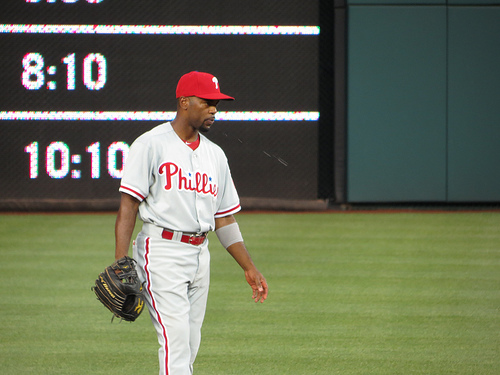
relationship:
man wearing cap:
[115, 70, 269, 374] [176, 69, 236, 103]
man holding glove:
[115, 70, 269, 374] [89, 256, 145, 324]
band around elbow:
[214, 220, 244, 250] [215, 214, 235, 229]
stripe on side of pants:
[142, 233, 170, 374] [131, 222, 210, 373]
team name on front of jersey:
[157, 160, 218, 196] [116, 120, 242, 236]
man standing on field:
[115, 70, 269, 374] [1, 207, 499, 374]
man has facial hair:
[115, 70, 269, 374] [198, 114, 217, 132]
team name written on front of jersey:
[157, 160, 218, 196] [116, 120, 242, 236]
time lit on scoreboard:
[18, 47, 108, 92] [1, 1, 332, 202]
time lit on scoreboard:
[23, 139, 131, 183] [1, 1, 332, 202]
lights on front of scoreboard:
[0, 1, 320, 180] [1, 1, 332, 202]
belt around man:
[159, 229, 207, 246] [115, 70, 269, 374]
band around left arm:
[214, 220, 244, 250] [214, 155, 257, 269]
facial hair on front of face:
[198, 114, 217, 132] [198, 96, 218, 131]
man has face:
[115, 70, 269, 374] [198, 96, 218, 131]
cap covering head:
[176, 69, 236, 103] [174, 71, 232, 133]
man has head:
[115, 70, 269, 374] [174, 71, 232, 133]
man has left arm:
[115, 70, 269, 374] [214, 155, 257, 269]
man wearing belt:
[115, 70, 269, 374] [159, 229, 207, 246]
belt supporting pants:
[159, 229, 207, 246] [131, 222, 210, 373]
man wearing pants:
[115, 70, 269, 374] [131, 222, 210, 373]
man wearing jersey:
[115, 70, 269, 374] [116, 120, 242, 236]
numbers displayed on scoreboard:
[17, 52, 130, 183] [1, 1, 332, 202]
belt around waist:
[159, 229, 207, 246] [138, 217, 213, 246]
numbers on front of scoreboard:
[17, 52, 130, 183] [1, 1, 332, 202]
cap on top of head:
[176, 69, 236, 103] [174, 71, 232, 133]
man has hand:
[115, 70, 269, 374] [243, 266, 270, 306]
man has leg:
[115, 70, 269, 374] [138, 232, 194, 374]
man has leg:
[115, 70, 269, 374] [189, 247, 209, 374]